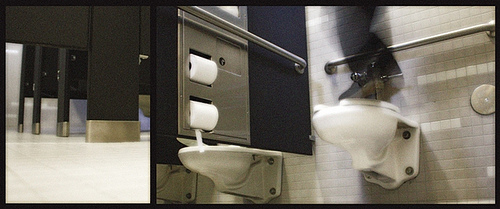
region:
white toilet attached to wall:
[304, 93, 425, 193]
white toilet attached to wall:
[169, 142, 284, 206]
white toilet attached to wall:
[146, 148, 198, 204]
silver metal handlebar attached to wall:
[321, 17, 497, 79]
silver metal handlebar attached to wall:
[172, 0, 308, 76]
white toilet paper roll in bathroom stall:
[187, 96, 219, 133]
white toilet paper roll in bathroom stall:
[185, 51, 220, 86]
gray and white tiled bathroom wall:
[149, 0, 496, 205]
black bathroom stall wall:
[155, 0, 317, 180]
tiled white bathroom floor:
[4, 115, 156, 207]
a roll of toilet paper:
[185, 55, 217, 84]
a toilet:
[174, 137, 289, 196]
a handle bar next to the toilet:
[184, 7, 309, 74]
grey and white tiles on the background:
[423, 105, 488, 166]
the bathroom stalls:
[6, 9, 140, 152]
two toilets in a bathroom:
[181, 60, 421, 189]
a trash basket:
[215, 39, 242, 74]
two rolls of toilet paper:
[189, 55, 216, 131]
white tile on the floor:
[11, 144, 134, 199]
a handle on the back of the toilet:
[326, 15, 497, 75]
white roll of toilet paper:
[173, 50, 223, 85]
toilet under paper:
[178, 133, 265, 188]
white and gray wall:
[425, 58, 463, 95]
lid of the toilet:
[339, 88, 396, 114]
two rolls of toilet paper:
[165, 38, 237, 147]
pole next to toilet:
[238, 25, 300, 91]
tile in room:
[26, 149, 99, 194]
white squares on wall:
[421, 68, 447, 90]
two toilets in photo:
[168, 63, 435, 198]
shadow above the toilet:
[367, 11, 414, 35]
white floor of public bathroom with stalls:
[5, 125, 148, 195]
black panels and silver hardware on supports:
[6, 5, 146, 140]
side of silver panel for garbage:
[212, 16, 247, 141]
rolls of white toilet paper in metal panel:
[180, 31, 215, 131]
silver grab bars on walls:
[186, 5, 491, 70]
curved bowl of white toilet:
[302, 95, 417, 185]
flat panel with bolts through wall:
[386, 125, 417, 175]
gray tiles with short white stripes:
[310, 10, 490, 196]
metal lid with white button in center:
[467, 76, 492, 113]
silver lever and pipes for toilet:
[347, 57, 405, 95]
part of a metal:
[361, 60, 396, 116]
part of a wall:
[278, 63, 296, 95]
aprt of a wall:
[441, 40, 483, 95]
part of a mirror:
[221, 108, 248, 143]